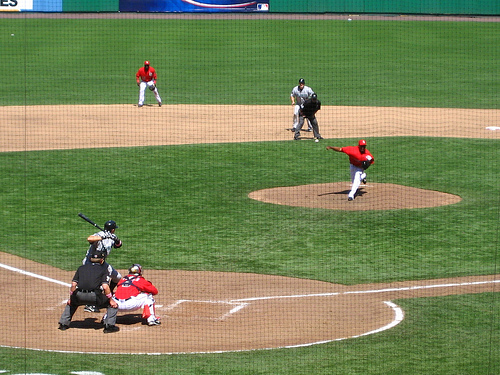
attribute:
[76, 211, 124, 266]
batter — anticipating, batting, ready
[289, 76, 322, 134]
runner — watching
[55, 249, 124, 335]
umpire — preparing, watching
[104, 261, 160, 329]
catcher — ready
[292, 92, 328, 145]
shortstop — standing, player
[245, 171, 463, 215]
mound — pitching, dirt, pitcher's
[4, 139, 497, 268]
infield — here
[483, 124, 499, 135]
base — second, white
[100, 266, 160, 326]
position — ready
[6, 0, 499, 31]
fence — meshed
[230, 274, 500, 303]
line — white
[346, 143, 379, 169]
top — red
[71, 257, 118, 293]
top — black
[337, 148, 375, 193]
uniform — red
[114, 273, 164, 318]
uniform — red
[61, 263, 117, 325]
uniform — umpire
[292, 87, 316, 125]
uniform — white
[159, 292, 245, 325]
marking — white